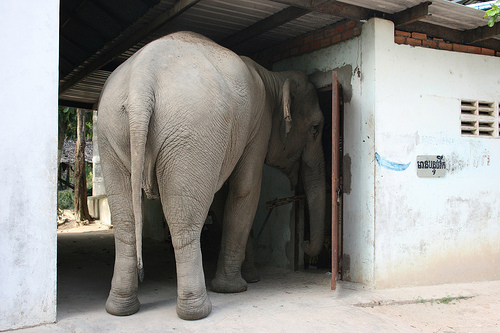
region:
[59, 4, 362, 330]
Large grey elephant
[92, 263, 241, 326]
Wide round elephant feet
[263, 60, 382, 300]
Doorway with open red door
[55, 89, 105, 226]
Tall tree behind building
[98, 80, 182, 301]
Long, grey hairless elephant tail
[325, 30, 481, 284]
White cement wall with a sign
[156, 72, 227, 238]
Wrinkled hairless skin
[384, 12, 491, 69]
Dark red bricks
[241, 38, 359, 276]
Elephant head with long nose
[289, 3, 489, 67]
Wooden ceiling frame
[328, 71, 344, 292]
faded red metal door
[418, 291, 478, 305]
patch of green grass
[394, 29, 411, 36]
red rectangle brick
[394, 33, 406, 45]
red rectangle brick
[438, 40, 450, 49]
red rectangle brick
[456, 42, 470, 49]
red rectangle brick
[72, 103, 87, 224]
long brown dead tree trunk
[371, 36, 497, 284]
dirty white old plastered wall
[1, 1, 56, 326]
dirty white old plastered wall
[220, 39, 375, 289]
dirty old white plastered wall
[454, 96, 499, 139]
Vents in the wall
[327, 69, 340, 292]
Red door which is open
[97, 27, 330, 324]
Elephant which is looking in the door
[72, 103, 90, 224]
Tree in the background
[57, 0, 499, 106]
Roof made of sheet metal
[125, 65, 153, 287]
The elephant's tail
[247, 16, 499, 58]
Bricks along the top of the building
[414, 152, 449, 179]
White sign on the wall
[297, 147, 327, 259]
The elephant's trunk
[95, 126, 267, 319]
The legs of the elephant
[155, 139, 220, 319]
long wrinkly elephant leg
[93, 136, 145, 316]
long wrinkly grey elephant leg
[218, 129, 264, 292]
long wrinkly grey elephant leg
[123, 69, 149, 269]
long wrinkly grey elephant tail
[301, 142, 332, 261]
long wrinkly grey elephant trunk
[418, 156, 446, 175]
gray and black sign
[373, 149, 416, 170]
light blue paint swoosh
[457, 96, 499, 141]
slatted white window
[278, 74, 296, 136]
wrinkly grey elephant ear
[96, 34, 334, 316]
wrinkly grey elephant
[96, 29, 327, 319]
the elephant is looking inside the house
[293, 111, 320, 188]
the elephant is smiling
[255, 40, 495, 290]
the building is white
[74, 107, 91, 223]
a tree is in the background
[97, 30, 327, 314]
the elephant is gray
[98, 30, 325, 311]
the elephant is large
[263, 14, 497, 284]
the building is in shambles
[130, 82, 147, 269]
the elephant has a long tale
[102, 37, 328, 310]
the elephant is wrinkly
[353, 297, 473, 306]
weeds grow in the ground